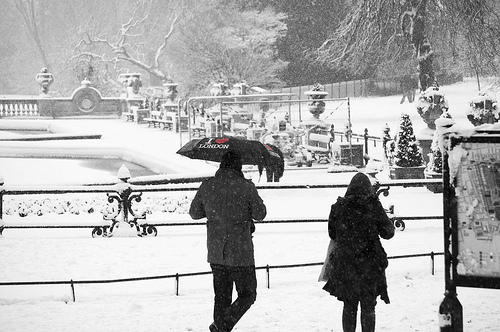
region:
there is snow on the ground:
[96, 235, 188, 324]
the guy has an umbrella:
[187, 165, 272, 330]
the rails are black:
[28, 177, 171, 247]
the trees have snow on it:
[67, 19, 241, 76]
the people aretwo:
[179, 160, 411, 302]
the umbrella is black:
[175, 93, 298, 168]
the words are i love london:
[191, 133, 294, 176]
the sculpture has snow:
[285, 87, 342, 138]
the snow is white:
[45, 244, 175, 267]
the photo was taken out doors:
[2, 60, 493, 326]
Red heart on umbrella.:
[209, 125, 240, 168]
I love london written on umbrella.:
[193, 118, 283, 204]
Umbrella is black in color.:
[159, 130, 388, 209]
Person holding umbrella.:
[178, 146, 308, 243]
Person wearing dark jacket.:
[197, 182, 299, 282]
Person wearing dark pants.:
[203, 282, 224, 314]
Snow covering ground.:
[77, 235, 251, 322]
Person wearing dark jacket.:
[337, 163, 367, 306]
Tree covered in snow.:
[376, 83, 446, 201]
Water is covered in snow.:
[23, 116, 109, 221]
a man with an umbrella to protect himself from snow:
[93, 80, 430, 330]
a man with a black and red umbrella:
[150, 84, 371, 330]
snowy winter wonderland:
[21, 32, 398, 329]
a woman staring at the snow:
[293, 127, 499, 303]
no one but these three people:
[24, 34, 339, 329]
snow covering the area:
[42, 39, 356, 329]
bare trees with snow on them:
[89, 17, 458, 256]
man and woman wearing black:
[178, 84, 472, 330]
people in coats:
[178, 118, 458, 330]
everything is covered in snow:
[298, 20, 498, 294]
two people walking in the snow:
[152, 129, 394, 328]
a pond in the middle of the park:
[1, 150, 145, 182]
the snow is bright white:
[28, 245, 195, 271]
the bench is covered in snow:
[0, 188, 203, 218]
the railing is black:
[2, 264, 215, 311]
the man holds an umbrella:
[155, 123, 286, 178]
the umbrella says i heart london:
[190, 130, 239, 152]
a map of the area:
[429, 123, 498, 302]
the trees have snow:
[387, 107, 427, 172]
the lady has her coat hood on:
[334, 167, 380, 209]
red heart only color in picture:
[133, 121, 334, 185]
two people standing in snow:
[151, 122, 413, 324]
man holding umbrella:
[156, 114, 285, 288]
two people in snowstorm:
[136, 107, 481, 307]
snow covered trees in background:
[26, 3, 498, 73]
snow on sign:
[411, 116, 497, 306]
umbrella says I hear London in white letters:
[142, 124, 302, 272]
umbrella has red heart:
[168, 114, 274, 196]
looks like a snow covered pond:
[20, 139, 170, 249]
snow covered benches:
[36, 74, 364, 179]